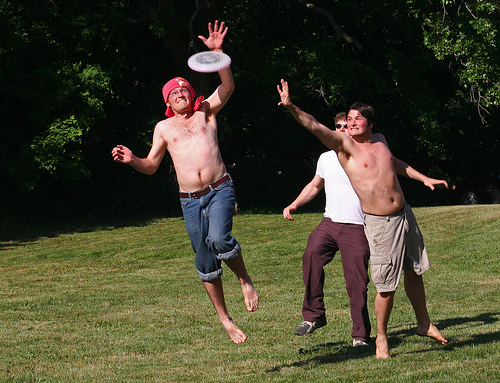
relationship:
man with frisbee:
[132, 80, 271, 268] [175, 38, 241, 98]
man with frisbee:
[276, 79, 448, 358] [181, 46, 238, 82]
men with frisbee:
[135, 84, 489, 304] [178, 27, 240, 78]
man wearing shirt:
[283, 112, 370, 347] [310, 139, 367, 223]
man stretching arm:
[271, 70, 469, 350] [261, 69, 346, 158]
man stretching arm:
[271, 70, 469, 350] [186, 7, 239, 118]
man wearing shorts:
[271, 70, 469, 350] [357, 207, 437, 294]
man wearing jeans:
[110, 19, 259, 345] [163, 170, 247, 287]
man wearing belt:
[110, 19, 259, 345] [174, 174, 244, 200]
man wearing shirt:
[110, 19, 259, 345] [153, 72, 205, 118]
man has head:
[110, 19, 259, 345] [150, 70, 200, 121]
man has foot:
[273, 101, 383, 355] [291, 298, 329, 345]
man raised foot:
[273, 101, 383, 355] [291, 298, 329, 345]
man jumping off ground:
[110, 19, 259, 345] [13, 283, 207, 380]